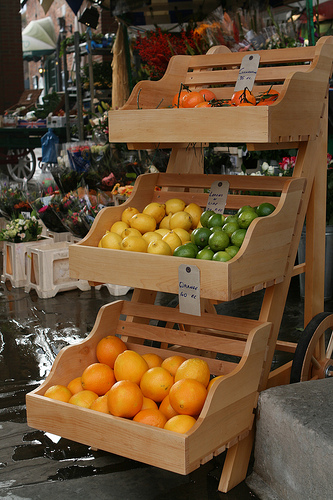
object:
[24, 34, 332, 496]
cart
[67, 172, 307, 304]
shelf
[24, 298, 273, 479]
shelf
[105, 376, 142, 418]
oranges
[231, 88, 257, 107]
tangerines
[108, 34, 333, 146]
shelf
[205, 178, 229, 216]
tag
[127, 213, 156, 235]
lemons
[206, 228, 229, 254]
limes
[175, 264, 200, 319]
tag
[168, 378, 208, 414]
oranges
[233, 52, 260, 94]
tag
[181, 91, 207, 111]
clementines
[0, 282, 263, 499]
floor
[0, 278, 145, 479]
water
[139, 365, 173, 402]
oranges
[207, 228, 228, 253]
lemons